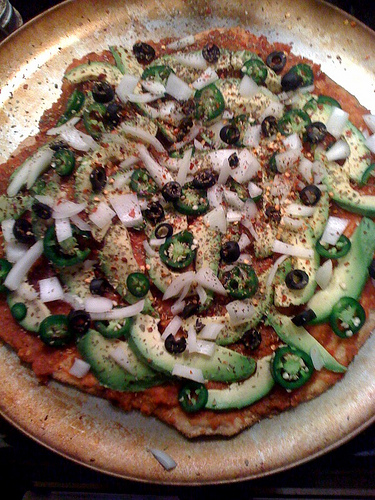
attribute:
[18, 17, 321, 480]
pizza — flatbread, sauce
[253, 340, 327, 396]
jalapeno — slice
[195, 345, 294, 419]
avocado — slice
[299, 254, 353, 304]
onion — small, pizza, slice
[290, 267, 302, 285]
olive — slice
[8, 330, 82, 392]
chili — sauce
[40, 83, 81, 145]
sauce — red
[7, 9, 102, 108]
plate — round, large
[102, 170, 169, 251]
pepper — red, green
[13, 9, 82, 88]
trey — pizza